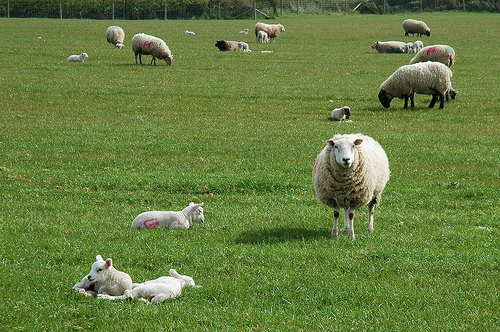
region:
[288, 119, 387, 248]
sheep in grassy field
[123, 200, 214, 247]
sheep in grassy field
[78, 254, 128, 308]
sheep in grassy field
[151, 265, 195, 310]
sheep in grassy field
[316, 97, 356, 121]
sheep in grassy field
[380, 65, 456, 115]
sheep in grassy field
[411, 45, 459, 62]
sheep in grassy field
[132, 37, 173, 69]
sheep in grassy field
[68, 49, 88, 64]
sheep in grassy field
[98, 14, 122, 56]
sheep in grassy field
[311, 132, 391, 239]
Sheep standing in the grass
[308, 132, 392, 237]
Sheep at attention in the grass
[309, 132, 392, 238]
Sheep standing erectly in a field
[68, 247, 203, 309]
Two lambs laying in the grass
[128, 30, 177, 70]
Sheep eating grass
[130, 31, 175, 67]
Grass being ate by a sheep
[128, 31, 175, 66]
Sheep feeding on grass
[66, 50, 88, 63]
Lamb sitting in grass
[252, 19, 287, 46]
Sheep and a lamb standing in grass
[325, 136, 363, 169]
Sheep's head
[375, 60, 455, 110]
Sheep with black face and legs.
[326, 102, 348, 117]
Lamb with black face.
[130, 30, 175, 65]
Sheep with red "H" on side.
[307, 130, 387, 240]
White sheep looking curiously at photographer.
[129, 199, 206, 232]
Lamb with red marking on side.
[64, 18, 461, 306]
Flock of sheep in green grass.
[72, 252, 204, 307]
Two lambs lying in the sun.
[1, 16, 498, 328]
Large grassy field full of sheep.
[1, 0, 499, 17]
Post and wire fence behind field.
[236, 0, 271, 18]
Corner fence post with diagonal bracing.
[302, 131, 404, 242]
white sheep standing in grass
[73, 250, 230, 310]
two baby sheep laying down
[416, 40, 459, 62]
sheep with red on his back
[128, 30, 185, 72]
sheep with red on his back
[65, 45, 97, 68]
white baby sheep laying down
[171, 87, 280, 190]
green grass the sheep our standing on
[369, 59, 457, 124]
white sheep eating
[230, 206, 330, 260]
shadow of sheep on the ground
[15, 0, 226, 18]
wooden fencing in the background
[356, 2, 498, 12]
green trees in the background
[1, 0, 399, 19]
A fence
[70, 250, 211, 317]
A couple of baby sheep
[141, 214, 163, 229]
A red marking on a baby sheep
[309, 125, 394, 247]
A full grown adult sheep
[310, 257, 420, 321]
A patch of green grass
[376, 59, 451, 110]
A sheep with a balck head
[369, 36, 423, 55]
A mom sheep with her babies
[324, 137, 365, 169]
A white sheeps head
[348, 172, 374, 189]
A white sheep's wool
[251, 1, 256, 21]
A wood fence post